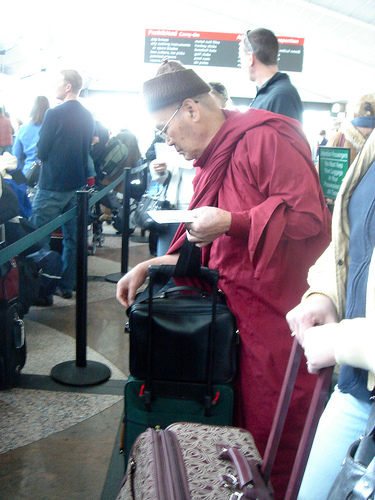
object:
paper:
[146, 208, 196, 224]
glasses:
[155, 100, 198, 138]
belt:
[0, 205, 78, 267]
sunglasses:
[243, 29, 252, 51]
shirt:
[37, 99, 93, 192]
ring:
[289, 327, 297, 335]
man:
[113, 60, 332, 497]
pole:
[75, 190, 87, 365]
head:
[237, 26, 279, 83]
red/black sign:
[143, 28, 303, 73]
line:
[0, 203, 80, 264]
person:
[30, 67, 94, 297]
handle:
[217, 444, 260, 497]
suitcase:
[114, 335, 334, 498]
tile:
[0, 385, 124, 453]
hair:
[29, 96, 49, 127]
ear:
[248, 52, 253, 65]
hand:
[185, 204, 231, 248]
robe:
[165, 107, 332, 499]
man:
[239, 27, 304, 125]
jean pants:
[30, 189, 76, 293]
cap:
[141, 58, 211, 113]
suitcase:
[118, 371, 234, 476]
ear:
[180, 96, 200, 123]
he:
[115, 60, 332, 498]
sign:
[318, 146, 350, 199]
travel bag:
[124, 284, 239, 384]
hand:
[116, 262, 148, 307]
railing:
[0, 158, 148, 384]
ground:
[0, 220, 157, 499]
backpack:
[17, 248, 64, 306]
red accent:
[212, 388, 219, 401]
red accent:
[136, 383, 145, 395]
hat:
[142, 58, 210, 112]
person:
[11, 95, 50, 177]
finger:
[297, 318, 311, 340]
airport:
[0, 0, 374, 497]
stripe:
[11, 372, 126, 394]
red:
[263, 357, 281, 377]